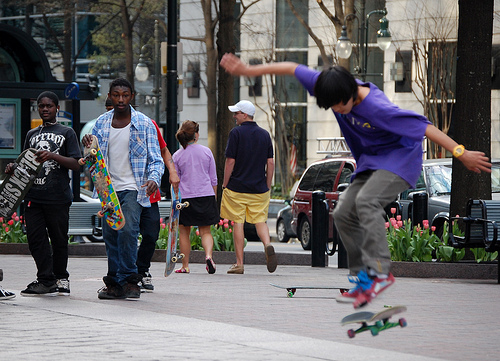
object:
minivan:
[288, 157, 360, 250]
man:
[218, 99, 278, 274]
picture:
[0, 0, 500, 361]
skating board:
[163, 186, 188, 277]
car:
[289, 156, 358, 250]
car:
[396, 156, 500, 247]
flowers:
[382, 205, 442, 263]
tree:
[386, 2, 456, 159]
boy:
[215, 51, 494, 310]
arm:
[388, 109, 462, 158]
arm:
[248, 60, 314, 88]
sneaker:
[354, 271, 395, 309]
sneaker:
[333, 277, 356, 305]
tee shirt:
[291, 63, 430, 191]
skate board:
[79, 135, 128, 230]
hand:
[79, 134, 96, 146]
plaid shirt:
[90, 105, 164, 207]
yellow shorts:
[219, 188, 270, 224]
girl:
[170, 120, 219, 275]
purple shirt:
[169, 144, 216, 196]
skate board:
[267, 282, 346, 298]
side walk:
[0, 233, 500, 361]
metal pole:
[312, 188, 326, 267]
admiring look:
[111, 90, 131, 112]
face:
[112, 86, 129, 114]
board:
[341, 304, 407, 339]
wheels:
[399, 318, 407, 329]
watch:
[448, 140, 466, 161]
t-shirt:
[22, 121, 84, 193]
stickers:
[4, 178, 22, 203]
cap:
[225, 99, 260, 118]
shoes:
[173, 265, 195, 276]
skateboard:
[336, 304, 412, 341]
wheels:
[346, 329, 356, 339]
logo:
[342, 114, 382, 132]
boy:
[85, 75, 167, 303]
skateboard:
[1, 145, 47, 234]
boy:
[4, 90, 85, 299]